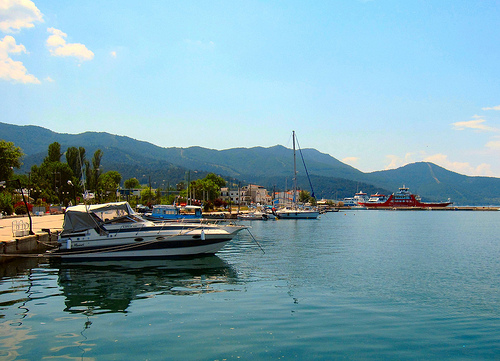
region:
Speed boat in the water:
[38, 196, 251, 273]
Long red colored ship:
[353, 182, 455, 214]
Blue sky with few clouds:
[0, 0, 499, 180]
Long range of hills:
[0, 120, 499, 203]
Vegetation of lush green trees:
[0, 137, 236, 206]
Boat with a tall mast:
[266, 126, 322, 222]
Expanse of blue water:
[1, 206, 498, 360]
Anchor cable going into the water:
[240, 222, 272, 261]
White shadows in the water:
[0, 304, 103, 360]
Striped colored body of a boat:
[51, 236, 238, 266]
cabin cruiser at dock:
[47, 201, 247, 256]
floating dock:
[0, 209, 128, 256]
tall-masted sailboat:
[270, 130, 318, 217]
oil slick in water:
[2, 303, 103, 360]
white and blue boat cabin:
[140, 196, 204, 219]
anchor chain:
[242, 225, 263, 251]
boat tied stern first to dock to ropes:
[44, 200, 266, 260]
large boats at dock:
[337, 187, 450, 209]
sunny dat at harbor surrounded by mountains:
[0, 119, 498, 355]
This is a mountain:
[20, 102, 52, 159]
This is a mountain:
[72, 109, 127, 178]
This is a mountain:
[117, 111, 171, 185]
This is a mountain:
[222, 116, 259, 191]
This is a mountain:
[224, 115, 266, 200]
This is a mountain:
[248, 118, 282, 207]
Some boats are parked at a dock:
[15, 23, 492, 343]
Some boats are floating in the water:
[35, 36, 495, 356]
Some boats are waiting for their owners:
[11, 102, 481, 347]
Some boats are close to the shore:
[6, 68, 487, 333]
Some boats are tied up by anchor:
[18, 57, 474, 352]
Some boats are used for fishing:
[5, 63, 470, 335]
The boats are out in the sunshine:
[21, 86, 457, 354]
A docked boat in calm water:
[30, 195, 277, 275]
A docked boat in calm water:
[24, 182, 271, 273]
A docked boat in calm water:
[42, 195, 272, 277]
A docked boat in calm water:
[32, 191, 271, 265]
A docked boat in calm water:
[35, 193, 272, 276]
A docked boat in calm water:
[23, 193, 269, 275]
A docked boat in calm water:
[38, 190, 271, 267]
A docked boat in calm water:
[27, 193, 270, 273]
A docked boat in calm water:
[38, 197, 271, 271]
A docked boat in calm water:
[27, 193, 267, 268]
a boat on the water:
[45, 204, 255, 266]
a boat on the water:
[138, 200, 205, 221]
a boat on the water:
[241, 207, 262, 222]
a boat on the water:
[275, 123, 324, 217]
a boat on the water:
[357, 182, 453, 207]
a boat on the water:
[345, 191, 365, 203]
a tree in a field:
[1, 140, 21, 191]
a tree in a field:
[19, 155, 74, 205]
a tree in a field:
[43, 141, 63, 168]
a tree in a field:
[64, 140, 82, 195]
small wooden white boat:
[59, 201, 247, 262]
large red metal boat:
[361, 191, 452, 208]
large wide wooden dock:
[0, 214, 64, 259]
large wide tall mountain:
[368, 161, 499, 202]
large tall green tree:
[0, 141, 23, 183]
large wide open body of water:
[0, 214, 499, 360]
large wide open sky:
[0, 1, 499, 175]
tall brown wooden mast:
[291, 134, 299, 209]